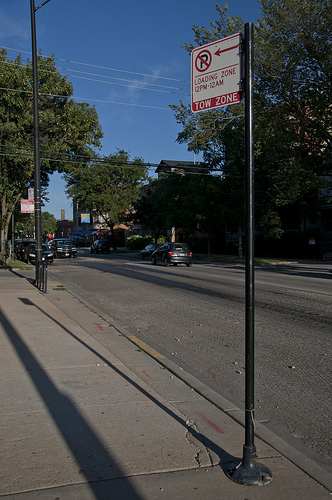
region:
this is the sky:
[87, 9, 179, 112]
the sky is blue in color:
[98, 11, 133, 35]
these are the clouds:
[123, 72, 147, 93]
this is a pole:
[242, 56, 273, 285]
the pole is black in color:
[242, 247, 259, 307]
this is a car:
[157, 237, 201, 265]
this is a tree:
[268, 28, 314, 166]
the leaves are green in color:
[270, 41, 295, 100]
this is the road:
[271, 280, 313, 353]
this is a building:
[164, 156, 204, 173]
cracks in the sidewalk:
[178, 427, 213, 464]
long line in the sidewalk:
[114, 463, 223, 475]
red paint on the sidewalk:
[194, 408, 230, 435]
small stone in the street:
[276, 358, 302, 373]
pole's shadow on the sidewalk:
[39, 393, 115, 449]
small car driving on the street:
[148, 236, 208, 265]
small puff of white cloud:
[99, 55, 176, 108]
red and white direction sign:
[180, 34, 256, 108]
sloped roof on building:
[152, 151, 216, 185]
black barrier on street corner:
[28, 253, 68, 297]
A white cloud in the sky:
[91, 57, 185, 117]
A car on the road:
[144, 236, 200, 279]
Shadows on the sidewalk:
[1, 297, 242, 498]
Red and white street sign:
[189, 31, 244, 113]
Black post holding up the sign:
[189, 20, 276, 488]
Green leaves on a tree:
[63, 149, 151, 227]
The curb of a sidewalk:
[48, 272, 330, 491]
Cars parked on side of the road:
[7, 231, 56, 266]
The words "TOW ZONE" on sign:
[188, 90, 242, 110]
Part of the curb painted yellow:
[122, 330, 168, 360]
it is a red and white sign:
[187, 33, 246, 112]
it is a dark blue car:
[152, 243, 195, 267]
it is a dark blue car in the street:
[152, 244, 198, 266]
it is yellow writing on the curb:
[131, 333, 167, 361]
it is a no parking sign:
[193, 34, 244, 112]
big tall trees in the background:
[0, 62, 92, 147]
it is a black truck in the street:
[53, 237, 83, 256]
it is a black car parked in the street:
[23, 243, 56, 263]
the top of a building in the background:
[160, 154, 210, 176]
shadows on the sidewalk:
[9, 293, 135, 426]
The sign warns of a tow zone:
[181, 40, 255, 114]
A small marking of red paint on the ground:
[196, 406, 226, 439]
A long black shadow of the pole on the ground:
[1, 294, 237, 469]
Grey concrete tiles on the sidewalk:
[0, 358, 196, 475]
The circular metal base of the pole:
[230, 450, 275, 485]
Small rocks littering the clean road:
[180, 325, 299, 383]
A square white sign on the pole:
[187, 37, 246, 107]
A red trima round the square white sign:
[193, 37, 243, 109]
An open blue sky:
[113, 114, 171, 161]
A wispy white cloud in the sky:
[107, 64, 170, 109]